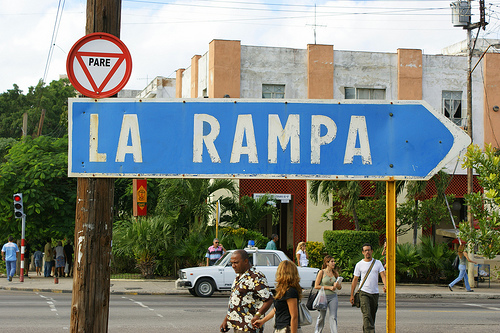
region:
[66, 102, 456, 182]
blue and white sign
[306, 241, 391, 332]
two people crossing the street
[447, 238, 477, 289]
woman walking along the sidewalk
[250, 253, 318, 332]
woman looking behind her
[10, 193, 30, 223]
stoplight that is red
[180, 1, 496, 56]
powerlines over the building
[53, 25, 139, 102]
red and white sign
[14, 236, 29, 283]
red and white stripes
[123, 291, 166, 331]
faded white line on the street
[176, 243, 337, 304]
white car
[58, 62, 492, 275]
a sign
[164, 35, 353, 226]
a sign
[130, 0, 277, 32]
The sky has clouds in it.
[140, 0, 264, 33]
The clouds are white.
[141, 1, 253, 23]
The sky is blue and white.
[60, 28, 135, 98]
The street sign is round.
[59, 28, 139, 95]
The sign is red and white.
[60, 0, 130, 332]
The pole is made of wood.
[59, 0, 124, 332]
The pole is made of brown wood.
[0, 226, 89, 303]
People are walking.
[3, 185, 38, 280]
A traffic light.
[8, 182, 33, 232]
The traffic light is red.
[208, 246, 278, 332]
man in brown floral shirt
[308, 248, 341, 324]
woman in green tank and jeans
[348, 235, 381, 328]
man with white shirt and messenger bag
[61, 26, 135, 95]
round red and white pare sign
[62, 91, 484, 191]
blue and white La Rampa sign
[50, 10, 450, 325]
telephone pole with signs attached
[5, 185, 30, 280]
red light across the street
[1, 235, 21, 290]
man walking past the red light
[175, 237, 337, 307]
small white car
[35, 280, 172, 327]
the white cross walk lines on the street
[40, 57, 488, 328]
People on the street in a foreign country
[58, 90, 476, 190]
Sign pointing to a location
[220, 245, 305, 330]
Man and woman walking together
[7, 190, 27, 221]
Streetlight at a city intersection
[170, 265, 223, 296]
Front of a white car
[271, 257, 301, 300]
Person with red colored hair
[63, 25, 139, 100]
Warning sign on a street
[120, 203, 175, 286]
Bush growing beside of a building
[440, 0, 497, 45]
Top of a power pole in a city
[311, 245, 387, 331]
Couple crossing the street together